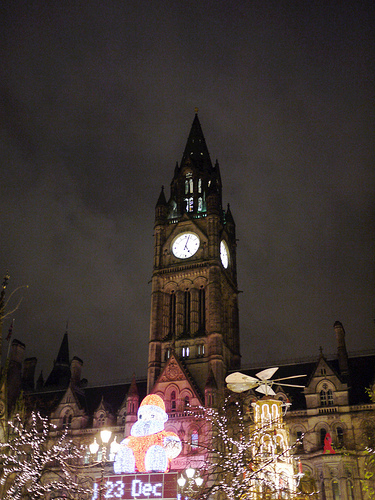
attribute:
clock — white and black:
[167, 227, 200, 259]